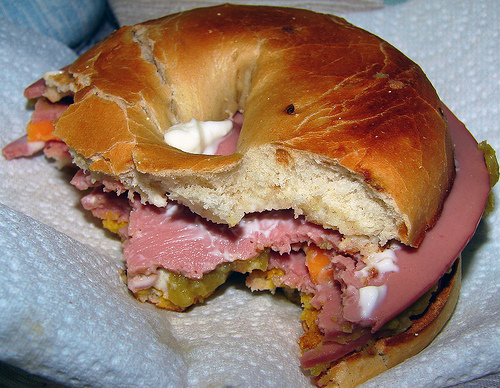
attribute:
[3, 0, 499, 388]
bagel — half eaten, toasted, sandwhich, thick, brown, partially eaten, bread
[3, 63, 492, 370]
bologna — sliced, pink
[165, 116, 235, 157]
mayonaise — white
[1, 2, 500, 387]
paper towel — white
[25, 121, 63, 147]
cheese — orange, yellow